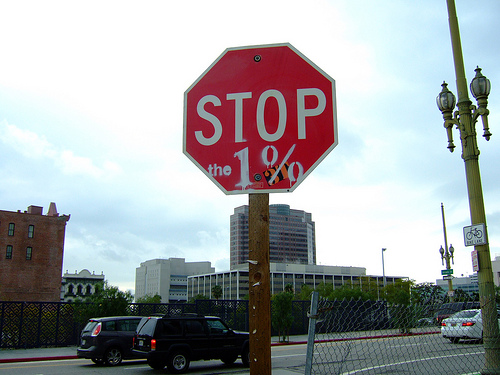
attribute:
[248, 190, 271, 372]
post — brown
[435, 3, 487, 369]
pole — tall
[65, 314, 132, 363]
suv — blue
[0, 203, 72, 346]
building — red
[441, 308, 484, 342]
car — white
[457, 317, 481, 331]
light — red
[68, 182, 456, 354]
building — bricks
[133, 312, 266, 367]
car — black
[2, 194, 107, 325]
building — brown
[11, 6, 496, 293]
sky — cloudy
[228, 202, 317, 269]
building — large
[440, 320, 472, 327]
lights — red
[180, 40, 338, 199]
sign — red, white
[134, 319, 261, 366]
vehicle — driving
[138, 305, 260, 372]
jeep — black